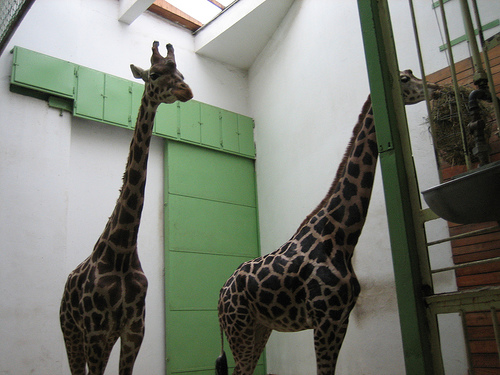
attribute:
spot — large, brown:
[308, 238, 335, 264]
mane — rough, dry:
[289, 87, 374, 245]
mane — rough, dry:
[92, 80, 149, 253]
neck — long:
[327, 116, 391, 246]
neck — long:
[111, 101, 162, 239]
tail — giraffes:
[203, 303, 244, 374]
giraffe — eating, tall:
[57, 36, 193, 373]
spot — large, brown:
[340, 177, 358, 199]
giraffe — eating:
[214, 62, 446, 372]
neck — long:
[86, 93, 161, 268]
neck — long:
[285, 81, 387, 253]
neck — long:
[117, 112, 162, 247]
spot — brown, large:
[305, 231, 335, 263]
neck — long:
[112, 98, 154, 244]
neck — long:
[312, 96, 389, 258]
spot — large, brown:
[132, 144, 146, 162]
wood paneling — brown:
[458, 308, 498, 373]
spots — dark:
[283, 243, 335, 301]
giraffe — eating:
[266, 90, 450, 325]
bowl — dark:
[424, 172, 499, 219]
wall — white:
[254, 0, 497, 365]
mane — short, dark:
[110, 78, 138, 226]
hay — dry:
[422, 72, 499, 160]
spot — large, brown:
[294, 229, 319, 255]